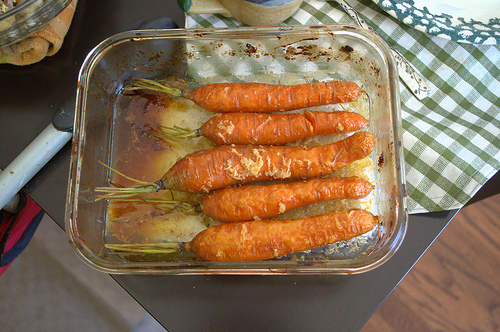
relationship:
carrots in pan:
[114, 79, 379, 261] [69, 24, 405, 278]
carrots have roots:
[114, 79, 379, 261] [98, 79, 204, 264]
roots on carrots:
[98, 79, 204, 264] [114, 79, 379, 261]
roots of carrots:
[98, 79, 204, 264] [114, 79, 379, 261]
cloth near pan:
[185, 1, 499, 213] [69, 24, 405, 278]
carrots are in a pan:
[114, 79, 379, 261] [69, 24, 405, 278]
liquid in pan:
[98, 79, 204, 264] [69, 24, 405, 278]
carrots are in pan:
[114, 79, 379, 261] [69, 24, 405, 278]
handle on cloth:
[333, 0, 429, 105] [185, 1, 499, 213]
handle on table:
[2, 99, 71, 218] [2, 2, 476, 332]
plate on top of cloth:
[373, 0, 498, 47] [185, 1, 499, 213]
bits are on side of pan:
[152, 35, 380, 83] [69, 24, 405, 278]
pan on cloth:
[69, 24, 405, 278] [185, 1, 499, 213]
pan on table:
[69, 24, 405, 278] [2, 2, 476, 332]